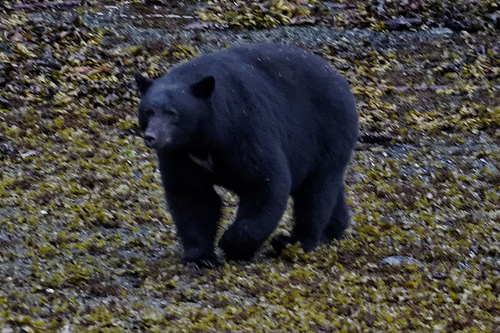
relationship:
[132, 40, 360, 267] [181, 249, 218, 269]
bear has paw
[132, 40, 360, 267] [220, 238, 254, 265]
bear has paw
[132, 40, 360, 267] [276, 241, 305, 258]
bear has paw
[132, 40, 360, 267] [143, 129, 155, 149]
bear has nose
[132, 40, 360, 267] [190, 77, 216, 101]
bear has ear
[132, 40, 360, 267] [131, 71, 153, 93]
bear has ear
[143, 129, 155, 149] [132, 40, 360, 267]
nose on bear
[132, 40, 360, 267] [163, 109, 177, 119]
bear has eye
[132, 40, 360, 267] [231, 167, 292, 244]
bear has leg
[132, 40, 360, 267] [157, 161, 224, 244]
bear has leg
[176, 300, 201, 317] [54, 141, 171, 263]
rocks next to leaves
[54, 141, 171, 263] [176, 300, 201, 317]
leaves next to rocks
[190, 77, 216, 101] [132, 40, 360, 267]
ear on bear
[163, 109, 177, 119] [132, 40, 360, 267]
eye on bear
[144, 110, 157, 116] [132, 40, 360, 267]
eye on bear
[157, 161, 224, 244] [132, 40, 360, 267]
leg on bear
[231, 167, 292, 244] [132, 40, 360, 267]
leg on bear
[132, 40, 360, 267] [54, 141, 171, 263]
bear walking on leaves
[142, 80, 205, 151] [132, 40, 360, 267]
head of bear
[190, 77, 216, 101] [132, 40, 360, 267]
ear of bear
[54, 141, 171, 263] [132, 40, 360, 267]
leaves under bear